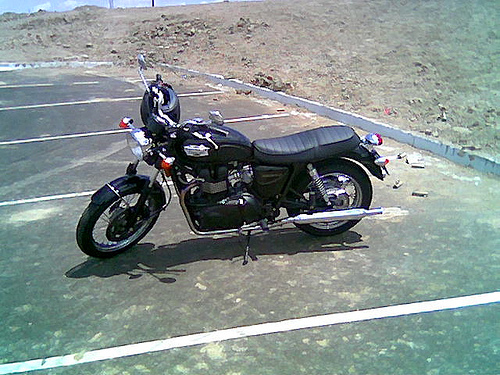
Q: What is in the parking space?
A: Motorcycle.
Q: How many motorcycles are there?
A: One.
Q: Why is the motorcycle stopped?
A: Parked.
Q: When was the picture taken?
A: Daytime.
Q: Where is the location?
A: Parking lot.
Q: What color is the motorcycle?
A: Black.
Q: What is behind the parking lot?
A: Grass.